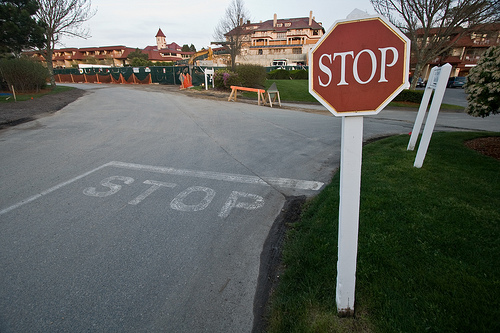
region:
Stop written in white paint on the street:
[80, 153, 325, 233]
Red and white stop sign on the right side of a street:
[308, 14, 388, 331]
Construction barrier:
[222, 82, 270, 106]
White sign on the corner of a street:
[386, 58, 465, 175]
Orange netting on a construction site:
[56, 69, 168, 89]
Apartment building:
[20, 41, 146, 74]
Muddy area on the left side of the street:
[3, 88, 101, 130]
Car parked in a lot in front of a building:
[448, 13, 480, 97]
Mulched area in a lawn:
[456, 123, 498, 170]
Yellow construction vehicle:
[181, 46, 241, 76]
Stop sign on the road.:
[289, 15, 449, 146]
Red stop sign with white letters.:
[273, 12, 445, 101]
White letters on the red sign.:
[280, 15, 476, 120]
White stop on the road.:
[40, 114, 290, 286]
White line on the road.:
[108, 122, 238, 222]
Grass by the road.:
[245, 203, 383, 291]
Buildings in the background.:
[103, 12, 325, 125]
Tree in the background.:
[405, 6, 497, 98]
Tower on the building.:
[143, 20, 185, 48]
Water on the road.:
[254, 170, 339, 265]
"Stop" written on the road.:
[67, 162, 308, 251]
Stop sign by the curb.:
[301, 12, 415, 133]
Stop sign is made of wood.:
[298, 25, 382, 327]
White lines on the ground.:
[11, 145, 312, 240]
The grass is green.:
[381, 166, 468, 306]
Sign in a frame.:
[423, 55, 457, 99]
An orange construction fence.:
[53, 71, 205, 96]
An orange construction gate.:
[220, 74, 270, 110]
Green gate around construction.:
[61, 55, 195, 92]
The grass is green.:
[399, 191, 499, 301]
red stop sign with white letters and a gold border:
[308, 16, 409, 117]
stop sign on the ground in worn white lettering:
[83, 172, 265, 217]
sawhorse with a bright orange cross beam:
[228, 85, 265, 102]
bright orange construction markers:
[53, 72, 157, 85]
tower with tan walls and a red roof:
[154, 32, 166, 49]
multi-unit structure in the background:
[36, 45, 135, 65]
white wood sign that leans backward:
[406, 61, 451, 168]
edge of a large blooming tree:
[463, 44, 499, 119]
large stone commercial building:
[226, 34, 323, 66]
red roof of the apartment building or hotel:
[146, 45, 188, 64]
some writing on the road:
[86, 157, 278, 214]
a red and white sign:
[285, 5, 420, 130]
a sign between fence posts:
[405, 49, 462, 187]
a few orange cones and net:
[47, 67, 160, 92]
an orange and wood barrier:
[216, 83, 270, 110]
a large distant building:
[198, 5, 327, 93]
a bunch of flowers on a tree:
[453, 46, 498, 116]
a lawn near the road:
[248, 82, 490, 331]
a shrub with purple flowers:
[204, 59, 241, 101]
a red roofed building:
[136, 26, 184, 69]